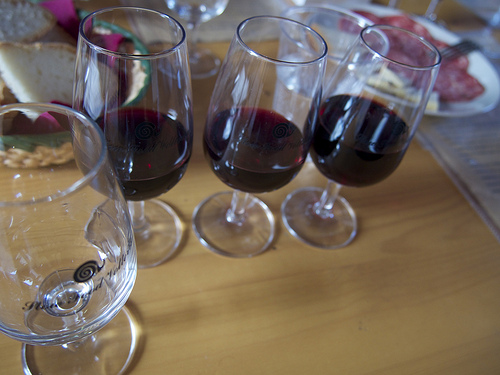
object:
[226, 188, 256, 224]
glass stem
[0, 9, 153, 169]
basket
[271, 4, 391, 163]
glass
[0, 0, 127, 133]
trim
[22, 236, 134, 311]
writing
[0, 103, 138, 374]
glass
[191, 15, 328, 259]
glass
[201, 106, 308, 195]
wine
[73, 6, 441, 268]
three glasses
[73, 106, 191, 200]
dark liquid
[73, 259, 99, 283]
black design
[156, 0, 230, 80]
glass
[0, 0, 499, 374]
table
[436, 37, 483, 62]
fork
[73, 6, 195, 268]
glass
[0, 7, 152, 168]
baske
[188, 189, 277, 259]
glass base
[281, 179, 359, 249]
base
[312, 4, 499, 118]
plate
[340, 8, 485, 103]
food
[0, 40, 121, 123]
bread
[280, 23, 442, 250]
glass